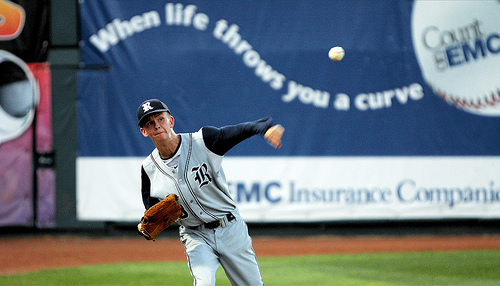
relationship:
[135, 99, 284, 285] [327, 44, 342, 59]
pitcher throwing baseball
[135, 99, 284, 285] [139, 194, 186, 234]
pitcher wearing baseball glove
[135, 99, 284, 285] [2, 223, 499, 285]
pitcher in baseball field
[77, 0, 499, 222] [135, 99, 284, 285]
advertisement behind pitcher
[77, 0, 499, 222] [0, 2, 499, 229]
advertisement hanging on wall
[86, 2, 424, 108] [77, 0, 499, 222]
text printed on advertisement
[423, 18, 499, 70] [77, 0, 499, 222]
text printed on advertisement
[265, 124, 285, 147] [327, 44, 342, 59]
hand throwing baseball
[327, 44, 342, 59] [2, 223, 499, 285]
baseball above baseball field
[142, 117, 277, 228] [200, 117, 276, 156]
jersey has sleeve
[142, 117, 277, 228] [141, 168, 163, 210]
jersey has sleeve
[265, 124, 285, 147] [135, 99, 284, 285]
hand of pitcher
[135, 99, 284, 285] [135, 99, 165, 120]
pitcher wearing cap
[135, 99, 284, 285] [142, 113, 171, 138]
pitcher has face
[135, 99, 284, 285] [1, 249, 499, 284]
pitcher standing on grass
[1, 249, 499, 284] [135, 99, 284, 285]
grass near pitcher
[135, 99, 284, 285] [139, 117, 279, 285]
pitcher wearing uniform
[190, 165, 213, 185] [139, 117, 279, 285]
letter printed on uniform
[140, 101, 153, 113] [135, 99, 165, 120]
letter printed on cap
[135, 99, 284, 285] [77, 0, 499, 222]
pitcher in front of advertisement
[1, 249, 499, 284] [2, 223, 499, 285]
grass growing on baseball field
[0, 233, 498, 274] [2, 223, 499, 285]
dirt on surface of baseball field